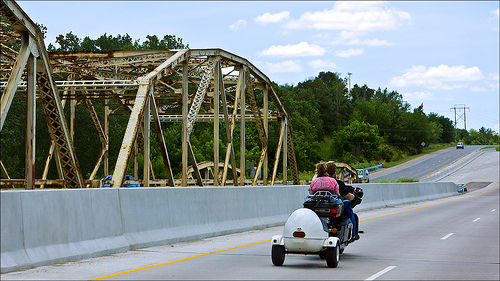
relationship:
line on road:
[364, 208, 497, 281] [0, 184, 498, 279]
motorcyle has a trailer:
[304, 185, 364, 254] [270, 208, 340, 268]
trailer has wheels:
[270, 208, 340, 268] [271, 244, 339, 267]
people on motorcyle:
[310, 160, 358, 237] [304, 185, 364, 254]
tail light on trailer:
[291, 231, 304, 238] [270, 208, 340, 268]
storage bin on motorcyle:
[303, 196, 344, 216] [304, 185, 364, 254]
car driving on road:
[457, 141, 463, 148] [324, 145, 491, 183]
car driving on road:
[353, 167, 370, 181] [324, 145, 491, 183]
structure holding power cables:
[448, 102, 469, 129] [195, 127, 496, 151]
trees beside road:
[2, 20, 500, 180] [324, 145, 491, 183]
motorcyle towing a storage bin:
[304, 185, 364, 254] [303, 196, 344, 216]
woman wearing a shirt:
[308, 161, 341, 197] [309, 175, 339, 194]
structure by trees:
[448, 102, 469, 129] [2, 20, 500, 180]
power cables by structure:
[195, 127, 496, 151] [448, 102, 469, 129]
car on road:
[457, 141, 463, 148] [324, 145, 491, 183]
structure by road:
[448, 102, 469, 129] [324, 145, 491, 183]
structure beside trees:
[448, 102, 469, 129] [2, 20, 500, 180]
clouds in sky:
[229, 2, 480, 105] [15, 0, 499, 137]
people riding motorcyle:
[310, 160, 358, 237] [304, 185, 364, 254]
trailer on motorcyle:
[270, 208, 340, 268] [304, 185, 364, 254]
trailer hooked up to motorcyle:
[270, 208, 340, 268] [304, 185, 364, 254]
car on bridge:
[100, 175, 140, 189] [1, 0, 299, 189]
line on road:
[85, 184, 498, 281] [0, 184, 498, 279]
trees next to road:
[2, 20, 500, 180] [324, 145, 491, 183]